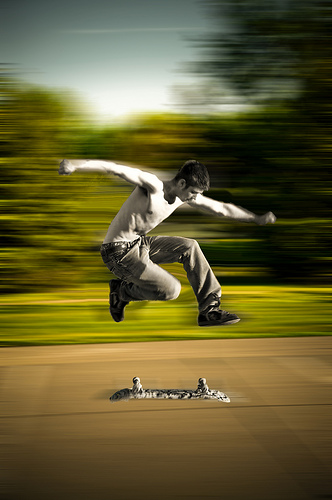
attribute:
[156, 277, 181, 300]
knee — bent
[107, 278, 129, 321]
shoe — black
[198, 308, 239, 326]
shoe — black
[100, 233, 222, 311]
jeans — black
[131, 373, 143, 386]
wheels — light colored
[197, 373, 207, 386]
wheels — light colored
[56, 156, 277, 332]
man — shirtless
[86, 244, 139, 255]
belt — black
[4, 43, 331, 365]
background — alive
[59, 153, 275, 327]
skateboarder — shirtless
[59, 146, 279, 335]
male — athlete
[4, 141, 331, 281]
trees — yellow, green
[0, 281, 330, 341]
grass — green, yellow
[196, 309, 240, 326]
sneaker — black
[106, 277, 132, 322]
sneaker — black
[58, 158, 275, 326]
guy — shirtless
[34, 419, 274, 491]
dirt — brown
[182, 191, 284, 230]
arm — extended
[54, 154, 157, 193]
arm — extended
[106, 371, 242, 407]
skateboard — upside down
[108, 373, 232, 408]
skateboard — upside down